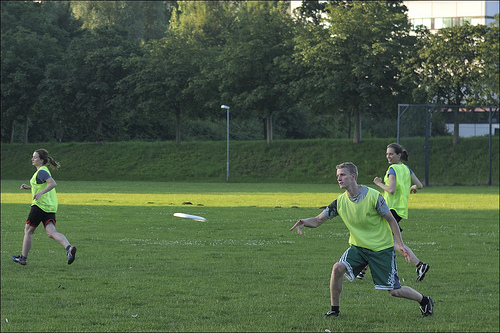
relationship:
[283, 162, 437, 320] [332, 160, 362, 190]
people has head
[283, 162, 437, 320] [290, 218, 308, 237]
people has right hand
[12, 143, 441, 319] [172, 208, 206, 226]
people playing frisbee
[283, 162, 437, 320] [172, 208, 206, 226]
people throwing frisbee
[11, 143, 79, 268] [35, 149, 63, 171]
girl has pony tail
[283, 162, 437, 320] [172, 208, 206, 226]
people throws frisbee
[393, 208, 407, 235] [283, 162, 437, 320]
shoes are on people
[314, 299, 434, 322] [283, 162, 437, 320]
shoes worn by people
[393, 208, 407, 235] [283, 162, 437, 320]
shoes worn by people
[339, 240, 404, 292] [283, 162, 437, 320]
shorts worn by people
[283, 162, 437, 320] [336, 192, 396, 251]
people wearing shirt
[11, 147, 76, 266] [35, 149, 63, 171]
girl has pony tail